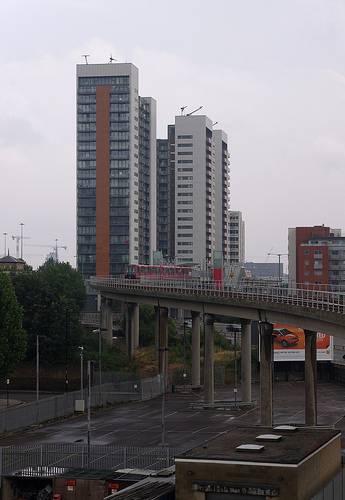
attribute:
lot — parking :
[12, 403, 221, 489]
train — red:
[121, 261, 195, 283]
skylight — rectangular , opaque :
[235, 439, 262, 455]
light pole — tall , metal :
[154, 347, 175, 456]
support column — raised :
[199, 311, 222, 412]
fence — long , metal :
[2, 440, 172, 473]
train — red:
[115, 254, 207, 297]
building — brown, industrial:
[160, 419, 335, 496]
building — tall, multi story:
[68, 66, 156, 257]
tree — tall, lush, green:
[20, 262, 77, 341]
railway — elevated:
[95, 277, 340, 403]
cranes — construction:
[9, 222, 79, 269]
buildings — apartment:
[283, 224, 342, 290]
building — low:
[135, 422, 342, 497]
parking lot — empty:
[46, 393, 256, 475]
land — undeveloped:
[117, 323, 250, 373]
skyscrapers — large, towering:
[71, 60, 177, 236]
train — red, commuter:
[109, 260, 198, 287]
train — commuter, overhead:
[106, 250, 222, 287]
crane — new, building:
[16, 224, 91, 281]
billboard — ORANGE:
[267, 323, 334, 359]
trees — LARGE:
[5, 255, 125, 371]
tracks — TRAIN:
[90, 265, 321, 315]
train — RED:
[122, 262, 190, 282]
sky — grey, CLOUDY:
[3, 5, 328, 270]